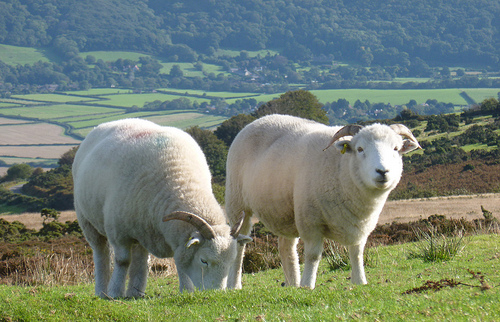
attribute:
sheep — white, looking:
[55, 94, 427, 299]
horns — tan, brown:
[162, 203, 256, 249]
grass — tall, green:
[2, 221, 499, 322]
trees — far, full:
[0, 1, 498, 90]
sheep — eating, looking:
[35, 102, 252, 315]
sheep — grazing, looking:
[185, 97, 410, 289]